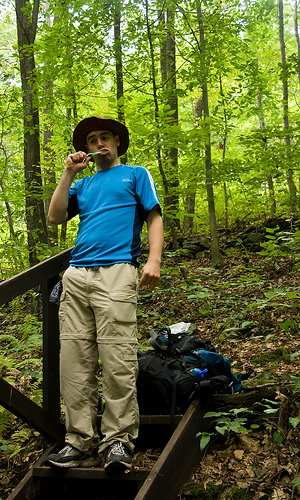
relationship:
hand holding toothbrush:
[66, 150, 91, 171] [78, 151, 105, 163]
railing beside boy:
[0, 244, 75, 445] [44, 113, 164, 471]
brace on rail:
[9, 383, 58, 429] [120, 321, 255, 452]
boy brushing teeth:
[47, 116, 164, 471] [98, 147, 113, 158]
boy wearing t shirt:
[47, 116, 164, 471] [67, 165, 157, 268]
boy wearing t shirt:
[47, 116, 164, 471] [58, 161, 162, 271]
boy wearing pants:
[47, 116, 164, 471] [58, 262, 145, 459]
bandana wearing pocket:
[47, 278, 65, 304] [61, 263, 72, 283]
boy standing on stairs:
[47, 116, 164, 471] [5, 359, 214, 498]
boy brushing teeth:
[47, 116, 164, 471] [98, 147, 109, 156]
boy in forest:
[47, 116, 164, 471] [6, 4, 299, 268]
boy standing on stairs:
[47, 116, 164, 471] [74, 464, 166, 492]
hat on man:
[72, 121, 118, 131] [60, 119, 159, 455]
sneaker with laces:
[42, 435, 102, 468] [59, 443, 73, 458]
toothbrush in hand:
[78, 151, 105, 163] [66, 147, 89, 174]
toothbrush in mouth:
[78, 151, 105, 163] [92, 147, 111, 156]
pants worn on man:
[58, 262, 145, 459] [48, 96, 159, 479]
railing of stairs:
[0, 215, 90, 423] [5, 378, 212, 499]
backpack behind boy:
[136, 327, 238, 415] [47, 116, 164, 471]